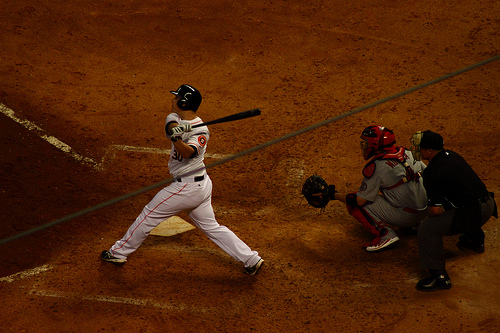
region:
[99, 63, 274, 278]
A batter swinging a baseball bat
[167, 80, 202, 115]
the batter's dark blue batting helmet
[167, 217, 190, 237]
home plate on the baseball field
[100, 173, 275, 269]
the batter's white uniform pants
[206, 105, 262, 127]
the batter's black baseball bat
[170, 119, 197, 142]
the batter's white batting gloves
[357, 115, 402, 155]
the catcher's red helmet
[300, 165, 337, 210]
the catcher's mitt extended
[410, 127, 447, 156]
the umpire's black hat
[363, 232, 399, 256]
the catcher's white shoes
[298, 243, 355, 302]
part of a ground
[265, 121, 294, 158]
part of a wire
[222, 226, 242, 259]
part of a trouser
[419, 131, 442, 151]
part of a cap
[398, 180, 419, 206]
part of a top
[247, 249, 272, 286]
sole of a shoe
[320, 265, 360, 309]
part of a ground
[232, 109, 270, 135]
part of a club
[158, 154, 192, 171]
part of a top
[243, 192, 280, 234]
part of a ground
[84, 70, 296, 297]
The batter is in white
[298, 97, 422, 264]
The catcher has a red helmet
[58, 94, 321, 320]
The white lines are covered by dirt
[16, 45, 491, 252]
A grey wire passes in the center of view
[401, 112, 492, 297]
The umpire crouches behind the catcher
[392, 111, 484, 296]
The umpire is wearing all black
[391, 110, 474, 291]
The umpire has a white mask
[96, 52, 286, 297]
The batter swings with a black bat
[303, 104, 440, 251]
The catcher is wearing a red chest guard and shin pads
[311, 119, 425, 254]
The catcher is wearing a grey shirt and pants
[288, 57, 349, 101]
part of a ground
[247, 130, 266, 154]
part of a wire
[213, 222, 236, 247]
part of a trouser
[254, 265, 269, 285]
part of a shoe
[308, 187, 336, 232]
part of a glove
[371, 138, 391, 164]
part of a helmet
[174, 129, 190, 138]
part of a glove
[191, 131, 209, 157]
part of a sleeve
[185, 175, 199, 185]
part of a waist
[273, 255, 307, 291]
part of a ground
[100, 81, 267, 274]
this is a man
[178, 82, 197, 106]
this is a helmet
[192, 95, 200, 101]
the helmet is black in color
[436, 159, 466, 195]
this is a t shirt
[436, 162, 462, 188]
the t shirt is black in color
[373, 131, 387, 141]
the helmet is red in color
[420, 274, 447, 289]
this is a shoe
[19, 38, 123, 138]
this is the playing ground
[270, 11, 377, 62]
the ground is bare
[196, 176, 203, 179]
this is a belt